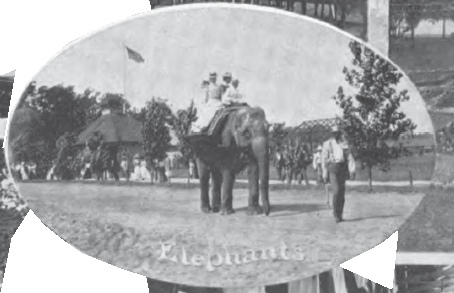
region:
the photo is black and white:
[0, 0, 453, 289]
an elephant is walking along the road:
[187, 103, 271, 215]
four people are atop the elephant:
[200, 68, 246, 103]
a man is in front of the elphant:
[322, 126, 353, 216]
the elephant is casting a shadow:
[223, 201, 333, 215]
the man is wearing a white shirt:
[319, 138, 355, 176]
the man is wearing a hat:
[330, 125, 340, 130]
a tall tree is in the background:
[334, 42, 407, 193]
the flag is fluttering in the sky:
[125, 46, 145, 66]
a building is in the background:
[75, 113, 174, 183]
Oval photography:
[0, 1, 443, 291]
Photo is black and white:
[2, 1, 441, 291]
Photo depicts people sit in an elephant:
[0, 3, 441, 291]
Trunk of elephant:
[243, 131, 276, 215]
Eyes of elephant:
[235, 121, 272, 139]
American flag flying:
[114, 35, 148, 107]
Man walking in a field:
[308, 117, 369, 229]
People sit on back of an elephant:
[188, 61, 247, 126]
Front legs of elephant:
[219, 161, 260, 221]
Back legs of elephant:
[188, 163, 226, 217]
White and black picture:
[6, 1, 445, 290]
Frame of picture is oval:
[0, 0, 446, 292]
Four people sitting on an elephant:
[180, 63, 278, 227]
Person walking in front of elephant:
[314, 119, 364, 233]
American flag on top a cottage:
[109, 35, 154, 115]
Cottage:
[64, 107, 173, 183]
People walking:
[276, 137, 321, 188]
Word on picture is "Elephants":
[0, 1, 450, 290]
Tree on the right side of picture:
[337, 43, 426, 199]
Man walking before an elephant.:
[321, 119, 357, 222]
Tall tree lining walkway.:
[333, 43, 419, 190]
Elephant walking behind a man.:
[185, 100, 271, 218]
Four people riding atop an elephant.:
[189, 67, 272, 218]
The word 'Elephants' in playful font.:
[160, 237, 309, 271]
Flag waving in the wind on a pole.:
[120, 44, 147, 113]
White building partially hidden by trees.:
[69, 108, 156, 183]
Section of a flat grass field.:
[35, 178, 197, 231]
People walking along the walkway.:
[21, 152, 150, 180]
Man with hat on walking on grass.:
[321, 125, 357, 224]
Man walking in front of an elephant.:
[304, 102, 368, 231]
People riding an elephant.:
[187, 69, 279, 218]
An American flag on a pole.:
[86, 28, 174, 129]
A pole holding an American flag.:
[116, 35, 130, 121]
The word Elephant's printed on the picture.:
[136, 228, 309, 285]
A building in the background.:
[63, 101, 168, 183]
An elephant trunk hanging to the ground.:
[252, 134, 279, 218]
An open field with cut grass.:
[21, 174, 397, 285]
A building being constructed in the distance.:
[274, 106, 366, 151]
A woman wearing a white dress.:
[182, 65, 226, 139]